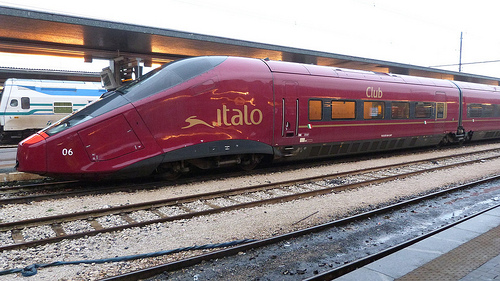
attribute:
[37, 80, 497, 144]
train — red, gold, passenger, long, shiny, rd, slek, sleek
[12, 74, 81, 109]
train — white, silver, blue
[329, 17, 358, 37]
sky — cloudy, gray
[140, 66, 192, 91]
window — black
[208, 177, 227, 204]
tracks — metal, gray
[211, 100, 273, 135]
logo — italo, gold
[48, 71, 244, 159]
nose — red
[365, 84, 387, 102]
word — gold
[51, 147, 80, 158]
umber — white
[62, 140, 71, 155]
number — 06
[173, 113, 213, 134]
bunny — gold